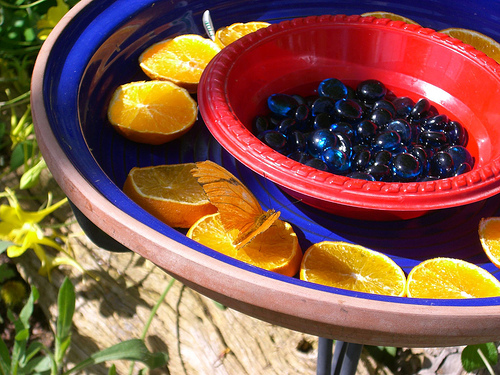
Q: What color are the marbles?
A: Blue.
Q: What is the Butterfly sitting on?
A: An orange.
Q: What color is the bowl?
A: Red.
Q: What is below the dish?
A: Plants.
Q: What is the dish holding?
A: Oranges.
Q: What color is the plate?
A: Blue.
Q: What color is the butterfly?
A: Orange.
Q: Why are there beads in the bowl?
A: Decorations.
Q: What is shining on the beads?
A: Sun.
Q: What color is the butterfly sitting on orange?
A: Orange.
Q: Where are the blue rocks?
A: Red bowl.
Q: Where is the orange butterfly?
A: On orange.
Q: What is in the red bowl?
A: Marbles.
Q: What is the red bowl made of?
A: Plastic.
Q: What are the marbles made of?
A: Glass.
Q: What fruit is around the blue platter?
A: Oranges.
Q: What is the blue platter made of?
A: Clay.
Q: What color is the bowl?
A: Red.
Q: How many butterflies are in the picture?
A: One.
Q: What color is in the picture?
A: Orange, red and green.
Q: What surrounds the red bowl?
A: Oranges.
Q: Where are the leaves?
A: Beneath the bowl.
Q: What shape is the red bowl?
A: Circular.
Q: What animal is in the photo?
A: Butterfly.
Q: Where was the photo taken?
A: In a garden.